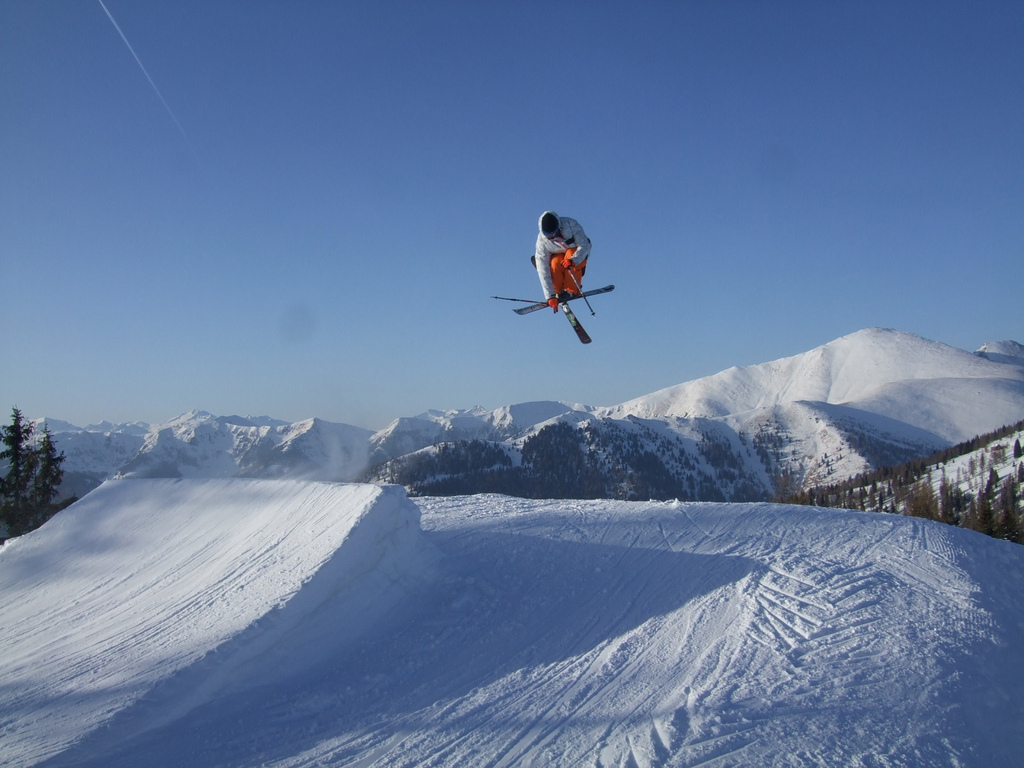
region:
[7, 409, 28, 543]
a tree in the woods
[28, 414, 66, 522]
a tree in the woods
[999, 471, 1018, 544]
a tree in the woods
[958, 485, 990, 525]
a tree in the woods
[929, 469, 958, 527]
a tree in the woods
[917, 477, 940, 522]
a tree in the woods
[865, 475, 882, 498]
a tree in the woods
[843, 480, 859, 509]
a tree in the woods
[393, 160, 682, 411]
the person is in the air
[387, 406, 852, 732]
the snow is white and fluffy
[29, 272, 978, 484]
the mountains have snow on them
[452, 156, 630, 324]
the person is bending down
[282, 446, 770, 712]
a shadow on the floor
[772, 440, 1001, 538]
the trees are brown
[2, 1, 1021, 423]
sky is clear and blue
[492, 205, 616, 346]
person is skiing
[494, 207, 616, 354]
person is wearing orange pants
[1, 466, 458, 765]
ramp is snow-covered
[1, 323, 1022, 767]
ground is white and snowy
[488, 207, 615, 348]
person is on skis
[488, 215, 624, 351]
person holding ski poles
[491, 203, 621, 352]
person wearing gray snow jacket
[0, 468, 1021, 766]
shadow of ski ramp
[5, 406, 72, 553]
tree is dark green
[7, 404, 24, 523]
a tree in the woods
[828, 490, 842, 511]
a tree in the woods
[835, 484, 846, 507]
a tree in the woods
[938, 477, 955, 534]
a tree in the woods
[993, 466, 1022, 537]
a tree in the woods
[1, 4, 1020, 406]
A smooth blue sky.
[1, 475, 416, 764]
A white snow ramp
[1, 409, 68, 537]
A dark tree next to a ramp.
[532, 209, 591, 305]
A man in orange pants in the air.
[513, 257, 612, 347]
Crossed skis in the air.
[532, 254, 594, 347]
Ski that is angled down the most.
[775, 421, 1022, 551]
Area with many trees up a hillside.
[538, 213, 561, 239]
Black hat on a head.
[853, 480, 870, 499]
pine tree on mountain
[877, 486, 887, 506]
pine tree on mountain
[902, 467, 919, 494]
pine tree on mountain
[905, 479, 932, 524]
pine tree on mountain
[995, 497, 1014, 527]
pine tree on mountain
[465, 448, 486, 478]
pine tree on mountain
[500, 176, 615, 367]
The man has a white jacket.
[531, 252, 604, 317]
The man has orange pants.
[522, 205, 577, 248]
The man has a black hat.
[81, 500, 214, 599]
The snow is white.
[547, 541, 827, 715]
The snow has tracks on it.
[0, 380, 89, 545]
The trees are near the snow.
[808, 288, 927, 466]
A mountain is in the distance.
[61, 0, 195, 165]
A jet leaves a trail.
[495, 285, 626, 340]
The man has black skiis.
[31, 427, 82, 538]
A tree in the woods.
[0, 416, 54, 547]
A tree in the woods.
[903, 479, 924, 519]
A tree in the woods.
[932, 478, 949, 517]
A tree in the woods.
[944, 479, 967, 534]
A tree in the woods.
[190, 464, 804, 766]
a shadow on snow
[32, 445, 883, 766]
snow on a slope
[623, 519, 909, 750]
tracks on the snow